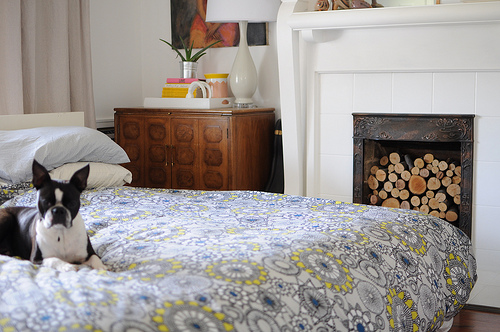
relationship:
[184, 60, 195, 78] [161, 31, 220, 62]
tin with greens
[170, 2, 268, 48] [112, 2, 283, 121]
picture on wall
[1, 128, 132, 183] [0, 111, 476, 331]
pillow on bed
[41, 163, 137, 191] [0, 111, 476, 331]
pillow on bed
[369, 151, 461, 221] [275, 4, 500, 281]
wood in fireplace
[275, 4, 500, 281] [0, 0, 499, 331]
fireplace in bedroom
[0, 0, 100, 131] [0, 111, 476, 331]
curtain behind bed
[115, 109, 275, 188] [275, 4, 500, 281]
furniture beside fireplace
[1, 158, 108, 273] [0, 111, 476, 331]
dog on bed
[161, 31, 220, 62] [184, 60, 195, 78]
greens in tin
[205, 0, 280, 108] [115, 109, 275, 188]
lamp on furniture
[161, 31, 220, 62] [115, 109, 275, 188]
greens on furniture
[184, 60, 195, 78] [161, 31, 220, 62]
tin holding greens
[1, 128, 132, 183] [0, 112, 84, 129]
pillow at top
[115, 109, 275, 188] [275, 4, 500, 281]
furniture next to fireplace